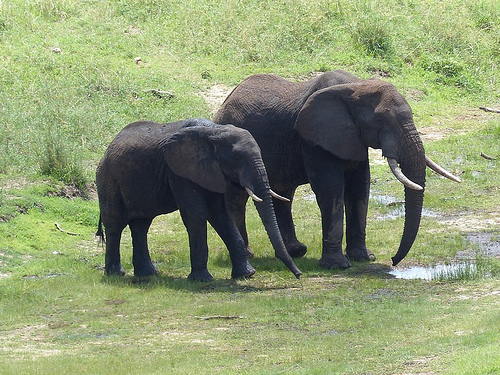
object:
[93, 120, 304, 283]
baby elephant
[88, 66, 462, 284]
elephant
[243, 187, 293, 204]
tusk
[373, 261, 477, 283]
puddle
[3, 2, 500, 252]
hill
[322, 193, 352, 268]
dried mud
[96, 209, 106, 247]
tail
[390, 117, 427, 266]
trunk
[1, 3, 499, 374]
grass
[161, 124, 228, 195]
ear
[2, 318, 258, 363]
dirt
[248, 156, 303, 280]
trunk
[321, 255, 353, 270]
foot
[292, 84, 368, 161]
ear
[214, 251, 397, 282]
shadow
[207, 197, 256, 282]
front leg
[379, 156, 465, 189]
tusk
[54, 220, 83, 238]
branch